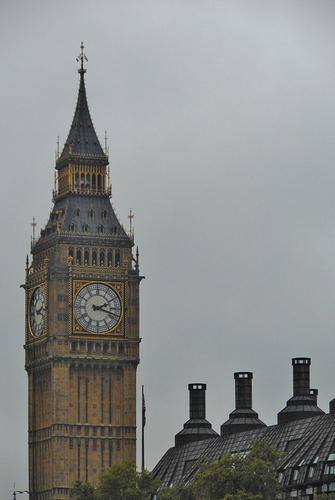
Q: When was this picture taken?
A: Daytime.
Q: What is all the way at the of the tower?
A: Weathervane.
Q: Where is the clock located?
A: Tower.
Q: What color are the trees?
A: Green.